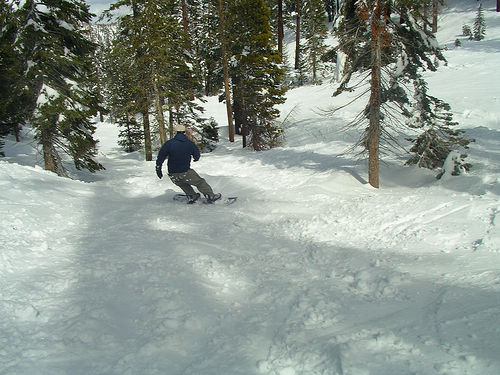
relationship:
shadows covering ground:
[0, 0, 499, 375] [6, 12, 485, 362]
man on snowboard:
[154, 116, 223, 205] [170, 191, 240, 208]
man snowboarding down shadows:
[154, 116, 223, 205] [0, 0, 499, 375]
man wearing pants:
[155, 124, 220, 201] [166, 170, 211, 200]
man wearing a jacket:
[155, 124, 220, 201] [154, 133, 199, 173]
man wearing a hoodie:
[155, 124, 220, 201] [156, 133, 201, 172]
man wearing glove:
[155, 124, 220, 201] [148, 165, 171, 186]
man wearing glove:
[155, 124, 220, 201] [155, 164, 165, 180]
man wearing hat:
[155, 124, 220, 201] [172, 120, 192, 139]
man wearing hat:
[154, 116, 223, 205] [176, 124, 186, 131]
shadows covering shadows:
[0, 0, 499, 375] [0, 0, 499, 375]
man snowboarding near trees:
[155, 124, 220, 201] [5, 2, 489, 182]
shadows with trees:
[0, 0, 499, 375] [4, 18, 494, 252]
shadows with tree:
[0, 0, 499, 375] [359, 14, 401, 193]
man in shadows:
[155, 124, 220, 201] [0, 0, 499, 375]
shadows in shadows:
[1, 2, 496, 371] [0, 0, 499, 375]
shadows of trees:
[1, 2, 496, 371] [7, 4, 384, 180]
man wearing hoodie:
[155, 124, 220, 201] [154, 127, 204, 172]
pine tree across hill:
[463, 13, 485, 42] [7, 12, 492, 142]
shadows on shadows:
[0, 0, 499, 375] [0, 0, 499, 375]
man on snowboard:
[155, 124, 220, 201] [172, 187, 238, 207]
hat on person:
[176, 124, 184, 131] [155, 125, 222, 203]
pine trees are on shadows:
[1, 0, 486, 189] [0, 0, 499, 375]